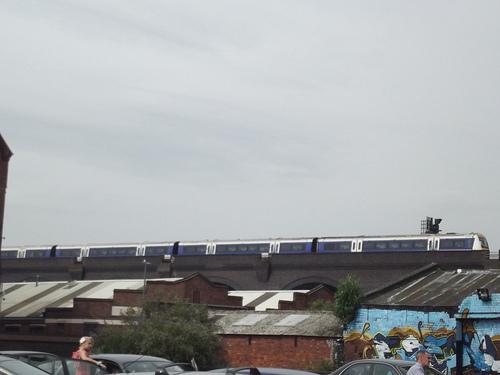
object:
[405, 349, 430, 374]
man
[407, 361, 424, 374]
shirt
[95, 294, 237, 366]
bush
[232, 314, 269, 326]
square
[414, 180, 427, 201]
ground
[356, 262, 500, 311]
roof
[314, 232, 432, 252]
train car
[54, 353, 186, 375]
car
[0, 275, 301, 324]
roof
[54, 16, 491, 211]
cloud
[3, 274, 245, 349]
building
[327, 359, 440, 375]
car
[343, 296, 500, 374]
graffiti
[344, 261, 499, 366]
building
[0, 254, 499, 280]
bridge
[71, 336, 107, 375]
woman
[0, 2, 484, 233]
sky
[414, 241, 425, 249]
window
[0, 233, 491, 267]
train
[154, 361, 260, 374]
rack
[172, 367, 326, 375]
car